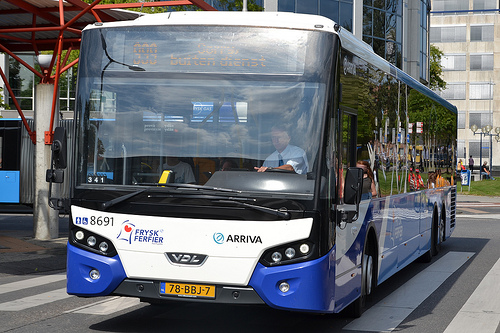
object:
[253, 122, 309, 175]
driver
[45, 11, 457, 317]
bus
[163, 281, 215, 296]
license plate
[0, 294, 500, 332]
road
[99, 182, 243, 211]
wipers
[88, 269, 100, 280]
headlight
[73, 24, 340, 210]
windsheild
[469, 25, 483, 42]
window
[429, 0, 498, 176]
building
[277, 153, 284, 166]
tie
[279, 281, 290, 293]
headlight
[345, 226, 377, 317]
wheel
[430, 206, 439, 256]
rear wheel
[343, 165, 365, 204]
mirror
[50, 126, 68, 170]
mirror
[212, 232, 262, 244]
logo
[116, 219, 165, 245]
frysk ferfier logo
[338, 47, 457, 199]
side windows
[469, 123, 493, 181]
lampost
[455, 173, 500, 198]
grass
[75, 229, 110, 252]
three lights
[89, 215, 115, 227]
bus number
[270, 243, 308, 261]
three lights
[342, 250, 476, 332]
white line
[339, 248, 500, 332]
crosswalk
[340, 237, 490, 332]
shadow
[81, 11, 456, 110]
roof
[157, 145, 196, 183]
person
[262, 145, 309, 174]
white shirt